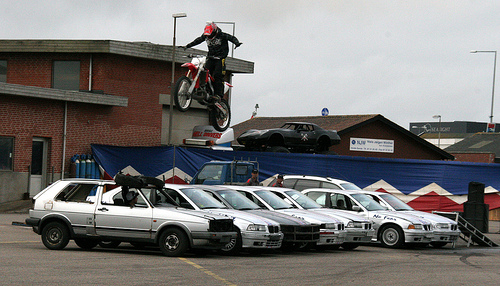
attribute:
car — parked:
[27, 176, 234, 255]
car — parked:
[88, 183, 284, 249]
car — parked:
[211, 183, 324, 249]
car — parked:
[265, 185, 376, 245]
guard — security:
[230, 158, 262, 189]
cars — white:
[288, 141, 458, 251]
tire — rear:
[38, 215, 69, 249]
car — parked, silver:
[28, 154, 227, 263]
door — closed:
[32, 137, 51, 194]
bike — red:
[174, 51, 233, 133]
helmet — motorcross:
[202, 22, 216, 37]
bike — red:
[154, 60, 221, 118]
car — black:
[233, 118, 344, 153]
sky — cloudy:
[265, 10, 475, 120]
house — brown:
[0, 33, 257, 214]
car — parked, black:
[235, 110, 350, 160]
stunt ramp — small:
[435, 209, 498, 249]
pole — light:
[469, 49, 499, 128]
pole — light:
[168, 12, 188, 144]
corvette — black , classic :
[239, 119, 340, 150]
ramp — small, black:
[441, 210, 497, 254]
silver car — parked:
[26, 170, 233, 250]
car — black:
[196, 176, 324, 247]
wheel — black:
[168, 71, 202, 114]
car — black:
[238, 121, 340, 151]